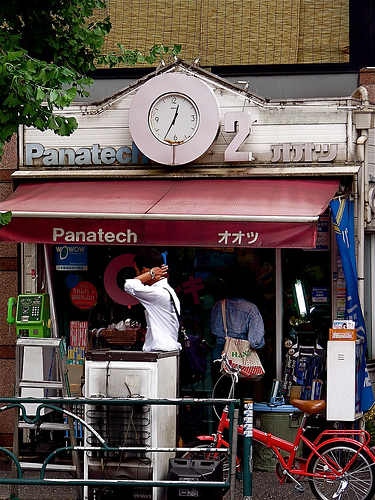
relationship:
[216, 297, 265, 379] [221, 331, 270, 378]
woman with bag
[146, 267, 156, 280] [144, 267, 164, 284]
watch on wrist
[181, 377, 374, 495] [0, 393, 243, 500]
bicycle on rail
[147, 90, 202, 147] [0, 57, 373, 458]
clock above storefront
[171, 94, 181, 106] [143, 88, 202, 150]
number on clock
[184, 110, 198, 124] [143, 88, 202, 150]
number on clock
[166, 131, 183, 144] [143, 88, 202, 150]
number on clock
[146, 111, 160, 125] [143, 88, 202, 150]
number on clock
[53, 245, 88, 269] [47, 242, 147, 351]
signs on window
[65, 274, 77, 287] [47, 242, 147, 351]
signs on window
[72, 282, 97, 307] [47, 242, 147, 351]
signs on window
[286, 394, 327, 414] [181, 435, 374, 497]
seat of bicycle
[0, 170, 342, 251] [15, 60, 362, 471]
canopy for storefront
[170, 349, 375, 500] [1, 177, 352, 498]
bicycle in front of store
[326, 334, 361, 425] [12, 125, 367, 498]
mail box for store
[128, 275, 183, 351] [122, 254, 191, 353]
shirt on man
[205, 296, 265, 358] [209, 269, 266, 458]
jacket on woman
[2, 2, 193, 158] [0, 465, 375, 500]
tree on ground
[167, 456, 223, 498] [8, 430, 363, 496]
tv on ground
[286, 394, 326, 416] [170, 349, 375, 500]
seat on bicycle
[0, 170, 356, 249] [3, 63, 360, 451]
canopy over business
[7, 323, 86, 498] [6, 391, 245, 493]
ladder leaning on railing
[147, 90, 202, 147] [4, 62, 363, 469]
clock on building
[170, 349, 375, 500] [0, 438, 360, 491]
bicycle parked on sidewalk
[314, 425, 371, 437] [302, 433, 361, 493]
rack on back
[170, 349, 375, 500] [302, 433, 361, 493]
bicycle has back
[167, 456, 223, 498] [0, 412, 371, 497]
tv on sidewalk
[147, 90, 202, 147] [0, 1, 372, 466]
clock on building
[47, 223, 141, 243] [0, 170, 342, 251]
word on canopy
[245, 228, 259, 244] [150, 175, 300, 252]
sign on awning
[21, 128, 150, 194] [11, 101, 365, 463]
sign top of building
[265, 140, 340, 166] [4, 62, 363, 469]
asian writing top of building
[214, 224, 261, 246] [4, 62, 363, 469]
asian writing top of building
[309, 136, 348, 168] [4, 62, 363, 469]
face top of building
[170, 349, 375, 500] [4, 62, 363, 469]
bicycle outside building